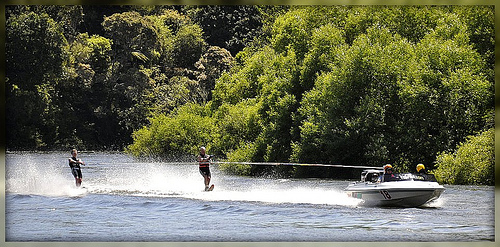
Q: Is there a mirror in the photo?
A: No, there are no mirrors.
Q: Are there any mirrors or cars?
A: No, there are no mirrors or cars.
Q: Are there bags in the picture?
A: No, there are no bags.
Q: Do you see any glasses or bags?
A: No, there are no bags or glasses.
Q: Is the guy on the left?
A: Yes, the guy is on the left of the image.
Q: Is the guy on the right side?
A: No, the guy is on the left of the image.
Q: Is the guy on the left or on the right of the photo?
A: The guy is on the left of the image.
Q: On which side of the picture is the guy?
A: The guy is on the left of the image.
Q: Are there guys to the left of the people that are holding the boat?
A: Yes, there is a guy to the left of the people.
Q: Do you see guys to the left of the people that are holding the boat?
A: Yes, there is a guy to the left of the people.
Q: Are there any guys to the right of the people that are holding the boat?
A: No, the guy is to the left of the people.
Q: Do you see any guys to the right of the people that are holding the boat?
A: No, the guy is to the left of the people.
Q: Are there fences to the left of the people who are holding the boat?
A: No, there is a guy to the left of the people.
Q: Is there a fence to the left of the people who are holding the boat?
A: No, there is a guy to the left of the people.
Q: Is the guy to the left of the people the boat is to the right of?
A: Yes, the guy is to the left of the people.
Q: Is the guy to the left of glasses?
A: No, the guy is to the left of the people.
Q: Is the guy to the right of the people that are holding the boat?
A: No, the guy is to the left of the people.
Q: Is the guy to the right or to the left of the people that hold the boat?
A: The guy is to the left of the people.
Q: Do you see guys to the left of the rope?
A: Yes, there is a guy to the left of the rope.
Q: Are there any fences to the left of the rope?
A: No, there is a guy to the left of the rope.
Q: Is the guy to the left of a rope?
A: Yes, the guy is to the left of a rope.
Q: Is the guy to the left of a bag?
A: No, the guy is to the left of a rope.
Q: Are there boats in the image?
A: Yes, there is a boat.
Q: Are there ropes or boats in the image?
A: Yes, there is a boat.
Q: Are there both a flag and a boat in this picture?
A: No, there is a boat but no flags.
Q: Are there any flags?
A: No, there are no flags.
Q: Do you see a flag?
A: No, there are no flags.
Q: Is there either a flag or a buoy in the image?
A: No, there are no flags or buoys.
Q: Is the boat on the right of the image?
A: Yes, the boat is on the right of the image.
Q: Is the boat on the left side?
A: No, the boat is on the right of the image.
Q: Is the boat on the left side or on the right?
A: The boat is on the right of the image.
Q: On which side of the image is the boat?
A: The boat is on the right of the image.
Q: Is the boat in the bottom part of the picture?
A: Yes, the boat is in the bottom of the image.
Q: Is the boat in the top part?
A: No, the boat is in the bottom of the image.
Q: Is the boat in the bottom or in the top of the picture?
A: The boat is in the bottom of the image.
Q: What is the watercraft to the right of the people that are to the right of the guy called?
A: The watercraft is a boat.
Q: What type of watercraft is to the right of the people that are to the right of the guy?
A: The watercraft is a boat.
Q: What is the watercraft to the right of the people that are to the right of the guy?
A: The watercraft is a boat.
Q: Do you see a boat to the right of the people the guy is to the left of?
A: Yes, there is a boat to the right of the people.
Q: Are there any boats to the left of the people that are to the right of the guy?
A: No, the boat is to the right of the people.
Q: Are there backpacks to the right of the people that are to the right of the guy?
A: No, there is a boat to the right of the people.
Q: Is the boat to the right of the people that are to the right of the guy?
A: Yes, the boat is to the right of the people.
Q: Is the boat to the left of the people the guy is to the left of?
A: No, the boat is to the right of the people.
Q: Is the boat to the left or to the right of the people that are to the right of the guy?
A: The boat is to the right of the people.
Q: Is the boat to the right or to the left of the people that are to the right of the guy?
A: The boat is to the right of the people.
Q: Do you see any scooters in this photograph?
A: No, there are no scooters.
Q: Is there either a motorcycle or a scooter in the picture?
A: No, there are no scooters or motorcycles.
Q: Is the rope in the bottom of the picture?
A: Yes, the rope is in the bottom of the image.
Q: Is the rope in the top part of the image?
A: No, the rope is in the bottom of the image.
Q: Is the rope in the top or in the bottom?
A: The rope is in the bottom of the image.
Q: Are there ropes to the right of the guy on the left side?
A: Yes, there is a rope to the right of the guy.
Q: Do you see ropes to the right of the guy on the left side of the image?
A: Yes, there is a rope to the right of the guy.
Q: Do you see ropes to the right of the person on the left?
A: Yes, there is a rope to the right of the guy.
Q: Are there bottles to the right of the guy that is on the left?
A: No, there is a rope to the right of the guy.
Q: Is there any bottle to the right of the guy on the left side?
A: No, there is a rope to the right of the guy.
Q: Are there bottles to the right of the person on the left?
A: No, there is a rope to the right of the guy.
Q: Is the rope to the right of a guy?
A: Yes, the rope is to the right of a guy.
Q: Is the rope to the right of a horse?
A: No, the rope is to the right of a guy.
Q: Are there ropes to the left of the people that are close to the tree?
A: Yes, there is a rope to the left of the people.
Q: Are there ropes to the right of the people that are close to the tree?
A: No, the rope is to the left of the people.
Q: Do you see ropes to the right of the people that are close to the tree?
A: No, the rope is to the left of the people.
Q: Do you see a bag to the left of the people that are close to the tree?
A: No, there is a rope to the left of the people.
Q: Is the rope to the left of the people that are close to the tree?
A: Yes, the rope is to the left of the people.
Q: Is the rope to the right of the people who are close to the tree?
A: No, the rope is to the left of the people.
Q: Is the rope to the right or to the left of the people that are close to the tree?
A: The rope is to the left of the people.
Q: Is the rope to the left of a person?
A: Yes, the rope is to the left of a person.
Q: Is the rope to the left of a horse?
A: No, the rope is to the left of a person.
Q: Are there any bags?
A: No, there are no bags.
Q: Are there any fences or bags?
A: No, there are no bags or fences.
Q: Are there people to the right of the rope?
A: Yes, there are people to the right of the rope.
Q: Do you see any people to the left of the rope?
A: No, the people are to the right of the rope.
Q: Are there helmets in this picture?
A: No, there are no helmets.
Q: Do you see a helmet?
A: No, there are no helmets.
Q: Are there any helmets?
A: No, there are no helmets.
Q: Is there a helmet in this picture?
A: No, there are no helmets.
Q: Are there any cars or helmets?
A: No, there are no helmets or cars.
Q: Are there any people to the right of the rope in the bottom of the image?
A: Yes, there is a person to the right of the rope.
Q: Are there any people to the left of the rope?
A: No, the person is to the right of the rope.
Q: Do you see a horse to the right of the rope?
A: No, there is a person to the right of the rope.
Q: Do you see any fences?
A: No, there are no fences.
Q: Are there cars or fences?
A: No, there are no fences or cars.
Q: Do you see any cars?
A: No, there are no cars.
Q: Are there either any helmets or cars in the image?
A: No, there are no cars or helmets.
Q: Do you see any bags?
A: No, there are no bags.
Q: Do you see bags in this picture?
A: No, there are no bags.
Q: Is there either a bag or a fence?
A: No, there are no bags or fences.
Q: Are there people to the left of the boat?
A: Yes, there are people to the left of the boat.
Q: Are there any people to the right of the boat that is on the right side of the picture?
A: No, the people are to the left of the boat.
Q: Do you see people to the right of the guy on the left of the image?
A: Yes, there are people to the right of the guy.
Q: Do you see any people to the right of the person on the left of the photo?
A: Yes, there are people to the right of the guy.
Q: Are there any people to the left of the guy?
A: No, the people are to the right of the guy.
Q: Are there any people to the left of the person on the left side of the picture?
A: No, the people are to the right of the guy.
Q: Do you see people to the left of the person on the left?
A: No, the people are to the right of the guy.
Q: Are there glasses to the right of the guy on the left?
A: No, there are people to the right of the guy.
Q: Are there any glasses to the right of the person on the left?
A: No, there are people to the right of the guy.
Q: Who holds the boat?
A: The people hold the boat.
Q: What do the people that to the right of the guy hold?
A: The people hold the boat.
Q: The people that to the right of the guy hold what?
A: The people hold the boat.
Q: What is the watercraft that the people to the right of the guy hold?
A: The watercraft is a boat.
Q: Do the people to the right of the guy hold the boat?
A: Yes, the people hold the boat.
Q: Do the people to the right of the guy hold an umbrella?
A: No, the people hold the boat.